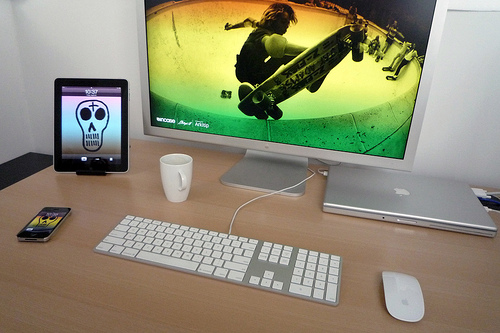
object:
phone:
[15, 205, 73, 242]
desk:
[2, 136, 498, 329]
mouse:
[380, 268, 425, 322]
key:
[247, 274, 259, 284]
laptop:
[321, 164, 499, 239]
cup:
[158, 152, 194, 202]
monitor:
[138, 0, 448, 173]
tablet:
[53, 78, 130, 174]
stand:
[76, 166, 104, 175]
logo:
[392, 187, 410, 197]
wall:
[13, 4, 113, 70]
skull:
[74, 99, 110, 152]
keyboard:
[92, 213, 344, 307]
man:
[223, 3, 330, 105]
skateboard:
[237, 23, 369, 121]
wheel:
[351, 47, 363, 62]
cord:
[318, 168, 329, 178]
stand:
[219, 148, 311, 198]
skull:
[35, 213, 57, 228]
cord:
[227, 167, 317, 236]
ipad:
[53, 77, 132, 176]